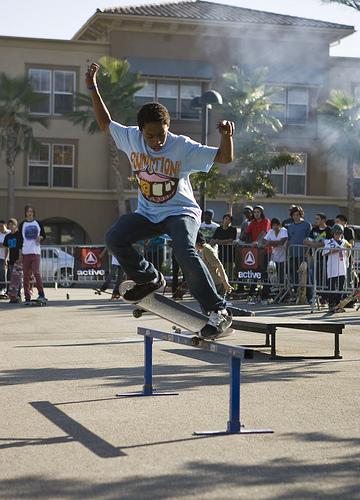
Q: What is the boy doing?
A: Skateboarding.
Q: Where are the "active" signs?
A: On the fence.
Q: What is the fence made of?
A: Metal.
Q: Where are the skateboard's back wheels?
A: In the air.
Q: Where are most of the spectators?
A: Behind the fence.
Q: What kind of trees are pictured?
A: Palm trees.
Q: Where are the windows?
A: On the building.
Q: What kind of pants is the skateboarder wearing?
A: Jeans.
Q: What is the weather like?
A: Sunny.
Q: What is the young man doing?
A: Skateboarding.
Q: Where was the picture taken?
A: In a skateboarding park.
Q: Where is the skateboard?
A: On a ramp.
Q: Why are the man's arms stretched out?
A: To keep balance.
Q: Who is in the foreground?
A: A boy.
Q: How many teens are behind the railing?
A: At least ten.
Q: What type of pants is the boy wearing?
A: Jeans.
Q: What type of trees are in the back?
A: Palms.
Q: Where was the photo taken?
A: Skate park.